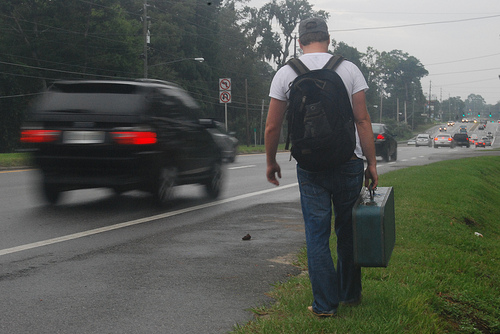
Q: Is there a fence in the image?
A: No, there are no fences.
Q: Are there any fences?
A: No, there are no fences.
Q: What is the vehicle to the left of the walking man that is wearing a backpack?
A: The vehicle is a car.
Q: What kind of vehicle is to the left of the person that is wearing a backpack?
A: The vehicle is a car.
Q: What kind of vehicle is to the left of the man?
A: The vehicle is a car.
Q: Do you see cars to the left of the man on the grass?
A: Yes, there is a car to the left of the man.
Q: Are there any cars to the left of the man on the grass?
A: Yes, there is a car to the left of the man.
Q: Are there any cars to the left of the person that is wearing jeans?
A: Yes, there is a car to the left of the man.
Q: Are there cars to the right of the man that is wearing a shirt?
A: No, the car is to the left of the man.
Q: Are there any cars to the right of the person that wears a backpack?
A: No, the car is to the left of the man.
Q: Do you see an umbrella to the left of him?
A: No, there is a car to the left of the man.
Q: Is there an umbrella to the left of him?
A: No, there is a car to the left of the man.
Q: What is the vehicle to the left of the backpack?
A: The vehicle is a car.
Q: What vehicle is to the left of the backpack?
A: The vehicle is a car.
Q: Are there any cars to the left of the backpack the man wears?
A: Yes, there is a car to the left of the backpack.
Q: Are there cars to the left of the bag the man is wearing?
A: Yes, there is a car to the left of the backpack.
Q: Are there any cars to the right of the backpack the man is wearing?
A: No, the car is to the left of the backpack.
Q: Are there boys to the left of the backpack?
A: No, there is a car to the left of the backpack.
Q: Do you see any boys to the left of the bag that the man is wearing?
A: No, there is a car to the left of the backpack.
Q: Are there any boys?
A: No, there are no boys.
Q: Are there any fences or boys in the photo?
A: No, there are no boys or fences.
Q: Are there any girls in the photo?
A: No, there are no girls.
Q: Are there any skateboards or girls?
A: No, there are no girls or skateboards.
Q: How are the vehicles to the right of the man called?
A: The vehicles are cars.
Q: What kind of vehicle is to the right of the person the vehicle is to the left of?
A: The vehicles are cars.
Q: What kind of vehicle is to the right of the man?
A: The vehicles are cars.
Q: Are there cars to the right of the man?
A: Yes, there are cars to the right of the man.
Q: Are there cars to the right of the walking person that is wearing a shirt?
A: Yes, there are cars to the right of the man.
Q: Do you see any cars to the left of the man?
A: No, the cars are to the right of the man.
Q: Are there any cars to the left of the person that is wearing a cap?
A: No, the cars are to the right of the man.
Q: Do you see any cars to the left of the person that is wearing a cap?
A: No, the cars are to the right of the man.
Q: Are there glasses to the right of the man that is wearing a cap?
A: No, there are cars to the right of the man.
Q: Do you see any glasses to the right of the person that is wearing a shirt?
A: No, there are cars to the right of the man.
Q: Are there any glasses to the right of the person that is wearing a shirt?
A: No, there are cars to the right of the man.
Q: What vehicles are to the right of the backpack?
A: The vehicles are cars.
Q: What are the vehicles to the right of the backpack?
A: The vehicles are cars.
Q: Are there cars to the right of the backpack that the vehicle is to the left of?
A: Yes, there are cars to the right of the backpack.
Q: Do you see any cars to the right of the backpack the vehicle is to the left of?
A: Yes, there are cars to the right of the backpack.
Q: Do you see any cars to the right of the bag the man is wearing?
A: Yes, there are cars to the right of the backpack.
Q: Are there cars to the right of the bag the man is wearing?
A: Yes, there are cars to the right of the backpack.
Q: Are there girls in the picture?
A: No, there are no girls.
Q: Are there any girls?
A: No, there are no girls.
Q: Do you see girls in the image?
A: No, there are no girls.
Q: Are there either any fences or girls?
A: No, there are no girls or fences.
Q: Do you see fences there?
A: No, there are no fences.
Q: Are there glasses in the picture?
A: No, there are no glasses.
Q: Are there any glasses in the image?
A: No, there are no glasses.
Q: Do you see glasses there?
A: No, there are no glasses.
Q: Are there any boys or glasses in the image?
A: No, there are no glasses or boys.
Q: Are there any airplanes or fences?
A: No, there are no fences or airplanes.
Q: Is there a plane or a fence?
A: No, there are no fences or airplanes.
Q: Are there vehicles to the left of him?
A: Yes, there is a vehicle to the left of the man.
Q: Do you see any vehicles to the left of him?
A: Yes, there is a vehicle to the left of the man.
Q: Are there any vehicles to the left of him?
A: Yes, there is a vehicle to the left of the man.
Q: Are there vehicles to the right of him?
A: No, the vehicle is to the left of the man.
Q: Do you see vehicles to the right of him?
A: No, the vehicle is to the left of the man.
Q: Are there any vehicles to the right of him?
A: No, the vehicle is to the left of the man.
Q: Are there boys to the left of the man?
A: No, there is a vehicle to the left of the man.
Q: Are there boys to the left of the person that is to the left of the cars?
A: No, there is a vehicle to the left of the man.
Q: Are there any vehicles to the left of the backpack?
A: Yes, there is a vehicle to the left of the backpack.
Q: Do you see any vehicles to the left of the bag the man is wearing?
A: Yes, there is a vehicle to the left of the backpack.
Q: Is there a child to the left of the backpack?
A: No, there is a vehicle to the left of the backpack.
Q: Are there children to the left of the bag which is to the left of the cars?
A: No, there is a vehicle to the left of the backpack.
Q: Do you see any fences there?
A: No, there are no fences.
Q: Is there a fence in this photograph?
A: No, there are no fences.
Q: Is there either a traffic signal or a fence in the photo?
A: No, there are no fences or traffic lights.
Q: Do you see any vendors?
A: No, there are no vendors.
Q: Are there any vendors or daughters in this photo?
A: No, there are no vendors or daughters.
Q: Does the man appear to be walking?
A: Yes, the man is walking.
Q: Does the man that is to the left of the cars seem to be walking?
A: Yes, the man is walking.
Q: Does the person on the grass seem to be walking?
A: Yes, the man is walking.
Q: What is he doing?
A: The man is walking.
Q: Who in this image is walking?
A: The man is walking.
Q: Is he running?
A: No, the man is walking.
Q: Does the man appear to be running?
A: No, the man is walking.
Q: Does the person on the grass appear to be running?
A: No, the man is walking.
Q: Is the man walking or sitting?
A: The man is walking.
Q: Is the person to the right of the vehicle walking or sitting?
A: The man is walking.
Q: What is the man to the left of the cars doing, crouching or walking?
A: The man is walking.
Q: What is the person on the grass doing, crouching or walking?
A: The man is walking.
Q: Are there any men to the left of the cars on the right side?
A: Yes, there is a man to the left of the cars.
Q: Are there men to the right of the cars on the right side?
A: No, the man is to the left of the cars.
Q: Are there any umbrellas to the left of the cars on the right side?
A: No, there is a man to the left of the cars.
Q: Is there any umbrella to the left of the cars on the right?
A: No, there is a man to the left of the cars.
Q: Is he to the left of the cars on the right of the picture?
A: Yes, the man is to the left of the cars.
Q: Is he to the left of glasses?
A: No, the man is to the left of the cars.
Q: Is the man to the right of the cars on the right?
A: No, the man is to the left of the cars.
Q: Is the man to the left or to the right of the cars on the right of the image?
A: The man is to the left of the cars.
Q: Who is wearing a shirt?
A: The man is wearing a shirt.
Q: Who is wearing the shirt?
A: The man is wearing a shirt.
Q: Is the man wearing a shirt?
A: Yes, the man is wearing a shirt.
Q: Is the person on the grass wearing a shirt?
A: Yes, the man is wearing a shirt.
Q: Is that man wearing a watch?
A: No, the man is wearing a shirt.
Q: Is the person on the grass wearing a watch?
A: No, the man is wearing a shirt.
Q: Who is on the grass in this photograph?
A: The man is on the grass.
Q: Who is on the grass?
A: The man is on the grass.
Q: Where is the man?
A: The man is on the grass.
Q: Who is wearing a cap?
A: The man is wearing a cap.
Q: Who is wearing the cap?
A: The man is wearing a cap.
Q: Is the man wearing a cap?
A: Yes, the man is wearing a cap.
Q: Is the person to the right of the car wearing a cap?
A: Yes, the man is wearing a cap.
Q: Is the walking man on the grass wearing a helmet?
A: No, the man is wearing a cap.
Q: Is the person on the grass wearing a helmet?
A: No, the man is wearing a cap.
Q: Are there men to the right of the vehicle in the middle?
A: Yes, there is a man to the right of the vehicle.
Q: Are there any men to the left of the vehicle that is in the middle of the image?
A: No, the man is to the right of the vehicle.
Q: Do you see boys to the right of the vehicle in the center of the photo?
A: No, there is a man to the right of the vehicle.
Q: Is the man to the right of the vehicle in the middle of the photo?
A: Yes, the man is to the right of the vehicle.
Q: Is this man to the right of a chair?
A: No, the man is to the right of the vehicle.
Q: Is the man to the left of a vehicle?
A: No, the man is to the right of a vehicle.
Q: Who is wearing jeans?
A: The man is wearing jeans.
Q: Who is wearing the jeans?
A: The man is wearing jeans.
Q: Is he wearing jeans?
A: Yes, the man is wearing jeans.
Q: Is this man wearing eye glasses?
A: No, the man is wearing jeans.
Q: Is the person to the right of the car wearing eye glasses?
A: No, the man is wearing jeans.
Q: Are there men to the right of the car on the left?
A: Yes, there is a man to the right of the car.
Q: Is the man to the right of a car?
A: Yes, the man is to the right of a car.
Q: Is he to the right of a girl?
A: No, the man is to the right of a car.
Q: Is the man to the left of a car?
A: No, the man is to the right of a car.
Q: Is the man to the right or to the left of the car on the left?
A: The man is to the right of the car.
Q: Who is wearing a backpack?
A: The man is wearing a backpack.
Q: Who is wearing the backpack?
A: The man is wearing a backpack.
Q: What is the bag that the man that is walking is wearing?
A: The bag is a backpack.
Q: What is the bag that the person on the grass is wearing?
A: The bag is a backpack.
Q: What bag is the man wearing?
A: The man is wearing a backpack.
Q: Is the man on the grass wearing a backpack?
A: Yes, the man is wearing a backpack.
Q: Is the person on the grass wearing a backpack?
A: Yes, the man is wearing a backpack.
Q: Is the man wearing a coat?
A: No, the man is wearing a backpack.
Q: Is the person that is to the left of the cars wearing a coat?
A: No, the man is wearing a backpack.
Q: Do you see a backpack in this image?
A: Yes, there is a backpack.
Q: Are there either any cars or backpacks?
A: Yes, there is a backpack.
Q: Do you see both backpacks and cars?
A: Yes, there are both a backpack and a car.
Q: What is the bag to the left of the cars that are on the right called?
A: The bag is a backpack.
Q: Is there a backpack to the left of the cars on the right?
A: Yes, there is a backpack to the left of the cars.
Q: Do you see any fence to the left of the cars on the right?
A: No, there is a backpack to the left of the cars.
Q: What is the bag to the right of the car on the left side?
A: The bag is a backpack.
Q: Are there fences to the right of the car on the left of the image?
A: No, there is a backpack to the right of the car.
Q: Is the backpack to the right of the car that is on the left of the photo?
A: Yes, the backpack is to the right of the car.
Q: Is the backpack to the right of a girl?
A: No, the backpack is to the right of the car.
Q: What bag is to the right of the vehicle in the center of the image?
A: The bag is a backpack.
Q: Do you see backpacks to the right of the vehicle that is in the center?
A: Yes, there is a backpack to the right of the vehicle.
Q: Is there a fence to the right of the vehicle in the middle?
A: No, there is a backpack to the right of the vehicle.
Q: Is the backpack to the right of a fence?
A: No, the backpack is to the right of the vehicle.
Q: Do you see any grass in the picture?
A: Yes, there is grass.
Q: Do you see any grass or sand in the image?
A: Yes, there is grass.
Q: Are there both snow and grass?
A: No, there is grass but no snow.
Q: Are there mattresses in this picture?
A: No, there are no mattresses.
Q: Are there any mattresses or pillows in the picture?
A: No, there are no mattresses or pillows.